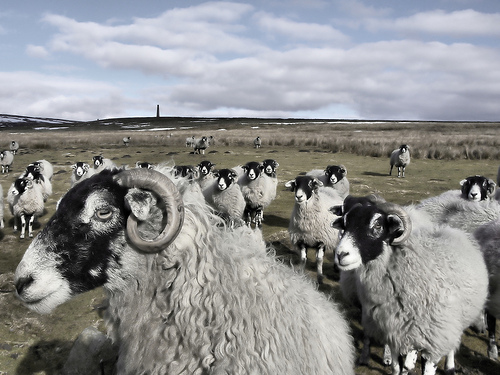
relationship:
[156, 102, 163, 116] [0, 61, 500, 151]
silo in distance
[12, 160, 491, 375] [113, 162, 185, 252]
ram has horn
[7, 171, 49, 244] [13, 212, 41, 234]
sheep has shadow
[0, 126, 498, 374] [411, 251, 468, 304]
sheep has fur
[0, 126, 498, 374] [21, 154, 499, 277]
sheep have horns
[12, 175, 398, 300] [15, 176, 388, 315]
faces have regions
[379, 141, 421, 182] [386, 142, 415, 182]
sheep with coat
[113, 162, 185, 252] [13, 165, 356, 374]
horn on sheep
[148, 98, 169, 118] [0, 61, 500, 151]
structure in distance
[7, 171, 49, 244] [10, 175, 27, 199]
sheep has face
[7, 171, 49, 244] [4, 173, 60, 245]
sheep has coat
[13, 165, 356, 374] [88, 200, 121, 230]
sheep has eye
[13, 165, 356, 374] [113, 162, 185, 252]
sheep has horn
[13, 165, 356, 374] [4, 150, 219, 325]
sheep has head